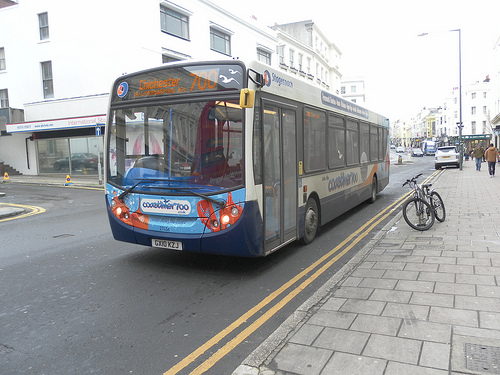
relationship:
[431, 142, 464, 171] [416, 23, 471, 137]
car parked next post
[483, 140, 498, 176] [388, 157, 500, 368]
person walking on sidewalk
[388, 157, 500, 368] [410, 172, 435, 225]
sidewalk has metal grate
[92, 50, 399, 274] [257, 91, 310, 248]
bus has glass door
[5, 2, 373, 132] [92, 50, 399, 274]
building behind bus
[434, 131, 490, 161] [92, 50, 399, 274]
storefront behind bus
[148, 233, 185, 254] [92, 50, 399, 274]
license plate on bus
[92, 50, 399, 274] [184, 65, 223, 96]
bus route 700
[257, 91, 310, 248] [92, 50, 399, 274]
doorway to bus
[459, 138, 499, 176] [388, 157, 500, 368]
people walking down street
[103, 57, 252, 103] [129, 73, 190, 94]
route to chichester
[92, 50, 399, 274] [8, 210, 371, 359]
bus on city street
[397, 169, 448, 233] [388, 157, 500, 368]
bike on sidewalk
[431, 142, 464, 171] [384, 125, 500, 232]
car parked halfway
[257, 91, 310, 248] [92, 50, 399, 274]
door to enter bus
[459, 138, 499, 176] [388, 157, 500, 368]
people walking on sidewalk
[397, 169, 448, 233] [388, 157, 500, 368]
bike in street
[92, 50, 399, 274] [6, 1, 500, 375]
bus in city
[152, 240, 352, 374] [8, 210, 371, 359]
lines in road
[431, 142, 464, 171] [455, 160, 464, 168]
car with wheels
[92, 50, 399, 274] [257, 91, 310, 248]
bus has big door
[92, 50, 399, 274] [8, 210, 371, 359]
bus in city street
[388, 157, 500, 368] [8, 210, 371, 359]
sidewalk tiled by street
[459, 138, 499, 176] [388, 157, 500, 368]
pedestrians walking on side  street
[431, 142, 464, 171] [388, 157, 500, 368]
car parked half on city street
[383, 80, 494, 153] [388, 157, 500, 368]
buildings line street